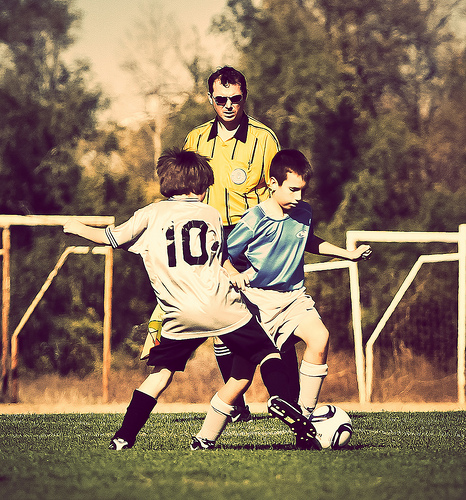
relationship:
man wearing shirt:
[179, 67, 299, 423] [183, 66, 281, 226]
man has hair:
[179, 67, 299, 423] [208, 66, 246, 96]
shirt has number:
[106, 196, 253, 341] [163, 219, 209, 268]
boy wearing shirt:
[195, 149, 372, 450] [226, 199, 315, 292]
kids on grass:
[62, 147, 317, 449] [2, 412, 464, 498]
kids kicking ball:
[62, 147, 372, 449] [307, 404, 353, 449]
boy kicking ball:
[195, 149, 372, 450] [307, 404, 353, 449]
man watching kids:
[179, 67, 299, 423] [62, 147, 372, 449]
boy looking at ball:
[195, 149, 372, 450] [307, 404, 353, 449]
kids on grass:
[62, 147, 372, 449] [2, 412, 464, 498]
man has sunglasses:
[179, 67, 299, 423] [211, 94, 243, 104]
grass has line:
[2, 412, 464, 498] [354, 426, 462, 438]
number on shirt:
[163, 219, 209, 268] [106, 196, 253, 341]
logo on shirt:
[229, 168, 248, 184] [183, 66, 281, 226]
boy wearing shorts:
[195, 149, 372, 450] [243, 287, 320, 352]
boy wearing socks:
[195, 149, 372, 450] [197, 393, 237, 442]